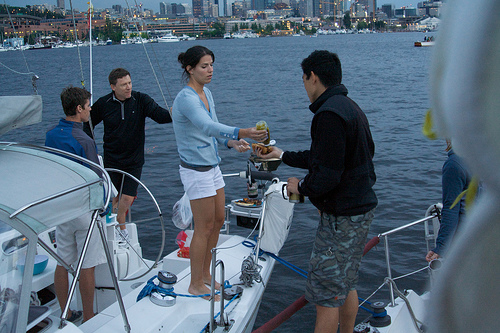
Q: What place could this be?
A: It is a harbor.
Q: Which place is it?
A: It is a harbor.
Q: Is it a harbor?
A: Yes, it is a harbor.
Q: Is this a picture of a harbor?
A: Yes, it is showing a harbor.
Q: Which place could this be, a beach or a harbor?
A: It is a harbor.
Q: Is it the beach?
A: No, it is the harbor.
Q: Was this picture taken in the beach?
A: No, the picture was taken in the harbor.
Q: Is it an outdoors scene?
A: Yes, it is outdoors.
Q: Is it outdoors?
A: Yes, it is outdoors.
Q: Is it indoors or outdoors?
A: It is outdoors.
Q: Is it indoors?
A: No, it is outdoors.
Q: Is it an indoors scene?
A: No, it is outdoors.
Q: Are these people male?
A: No, they are both male and female.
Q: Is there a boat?
A: Yes, there is a boat.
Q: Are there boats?
A: Yes, there is a boat.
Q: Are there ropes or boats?
A: Yes, there is a boat.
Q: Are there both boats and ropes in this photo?
A: Yes, there are both a boat and a rope.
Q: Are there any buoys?
A: No, there are no buoys.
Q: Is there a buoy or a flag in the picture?
A: No, there are no buoys or flags.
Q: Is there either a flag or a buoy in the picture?
A: No, there are no buoys or flags.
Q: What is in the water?
A: The boat is in the water.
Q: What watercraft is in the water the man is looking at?
A: The watercraft is a boat.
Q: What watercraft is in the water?
A: The watercraft is a boat.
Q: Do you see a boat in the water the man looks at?
A: Yes, there is a boat in the water.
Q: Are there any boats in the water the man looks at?
A: Yes, there is a boat in the water.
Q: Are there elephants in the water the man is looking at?
A: No, there is a boat in the water.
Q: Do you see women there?
A: Yes, there is a woman.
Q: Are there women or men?
A: Yes, there is a woman.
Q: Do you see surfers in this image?
A: No, there are no surfers.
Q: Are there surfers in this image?
A: No, there are no surfers.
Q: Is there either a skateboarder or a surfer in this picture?
A: No, there are no surfers or skateboarders.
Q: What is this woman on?
A: The woman is on the boat.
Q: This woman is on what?
A: The woman is on the boat.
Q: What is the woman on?
A: The woman is on the boat.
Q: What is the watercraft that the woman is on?
A: The watercraft is a boat.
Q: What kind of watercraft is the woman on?
A: The woman is on the boat.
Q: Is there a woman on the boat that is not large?
A: Yes, there is a woman on the boat.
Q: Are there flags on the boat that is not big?
A: No, there is a woman on the boat.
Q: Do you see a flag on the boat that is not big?
A: No, there is a woman on the boat.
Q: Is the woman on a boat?
A: Yes, the woman is on a boat.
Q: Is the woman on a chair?
A: No, the woman is on a boat.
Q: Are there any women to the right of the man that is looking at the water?
A: Yes, there is a woman to the right of the man.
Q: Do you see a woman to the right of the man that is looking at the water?
A: Yes, there is a woman to the right of the man.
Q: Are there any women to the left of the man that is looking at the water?
A: No, the woman is to the right of the man.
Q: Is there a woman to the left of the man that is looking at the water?
A: No, the woman is to the right of the man.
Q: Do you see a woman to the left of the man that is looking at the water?
A: No, the woman is to the right of the man.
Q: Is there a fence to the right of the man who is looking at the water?
A: No, there is a woman to the right of the man.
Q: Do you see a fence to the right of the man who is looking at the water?
A: No, there is a woman to the right of the man.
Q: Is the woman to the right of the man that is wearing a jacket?
A: Yes, the woman is to the right of the man.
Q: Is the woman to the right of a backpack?
A: No, the woman is to the right of the man.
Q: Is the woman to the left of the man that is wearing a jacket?
A: No, the woman is to the right of the man.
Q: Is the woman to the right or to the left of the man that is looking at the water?
A: The woman is to the right of the man.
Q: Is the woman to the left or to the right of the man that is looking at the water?
A: The woman is to the right of the man.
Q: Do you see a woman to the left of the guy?
A: Yes, there is a woman to the left of the guy.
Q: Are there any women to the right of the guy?
A: No, the woman is to the left of the guy.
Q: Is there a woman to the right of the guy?
A: No, the woman is to the left of the guy.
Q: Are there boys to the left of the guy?
A: No, there is a woman to the left of the guy.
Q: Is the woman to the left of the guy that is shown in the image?
A: Yes, the woman is to the left of the guy.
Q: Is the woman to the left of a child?
A: No, the woman is to the left of the guy.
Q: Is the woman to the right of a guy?
A: No, the woman is to the left of a guy.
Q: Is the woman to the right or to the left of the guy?
A: The woman is to the left of the guy.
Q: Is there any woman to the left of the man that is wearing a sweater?
A: Yes, there is a woman to the left of the man.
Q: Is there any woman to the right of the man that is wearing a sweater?
A: No, the woman is to the left of the man.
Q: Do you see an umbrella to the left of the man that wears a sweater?
A: No, there is a woman to the left of the man.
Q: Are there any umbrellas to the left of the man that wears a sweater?
A: No, there is a woman to the left of the man.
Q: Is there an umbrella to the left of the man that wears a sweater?
A: No, there is a woman to the left of the man.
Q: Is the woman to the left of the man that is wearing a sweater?
A: Yes, the woman is to the left of the man.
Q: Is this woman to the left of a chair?
A: No, the woman is to the left of the man.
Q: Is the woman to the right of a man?
A: No, the woman is to the left of a man.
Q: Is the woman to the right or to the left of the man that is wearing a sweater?
A: The woman is to the left of the man.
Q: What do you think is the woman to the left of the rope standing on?
A: The woman is standing on the boat.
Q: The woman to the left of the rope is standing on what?
A: The woman is standing on the boat.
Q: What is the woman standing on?
A: The woman is standing on the boat.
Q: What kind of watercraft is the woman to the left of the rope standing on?
A: The woman is standing on the boat.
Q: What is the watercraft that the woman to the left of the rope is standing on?
A: The watercraft is a boat.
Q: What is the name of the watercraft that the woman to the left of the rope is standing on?
A: The watercraft is a boat.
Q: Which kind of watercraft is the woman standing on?
A: The woman is standing on the boat.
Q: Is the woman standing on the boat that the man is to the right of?
A: Yes, the woman is standing on the boat.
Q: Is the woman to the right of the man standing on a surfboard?
A: No, the woman is standing on the boat.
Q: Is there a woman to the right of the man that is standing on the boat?
A: Yes, there is a woman to the right of the man.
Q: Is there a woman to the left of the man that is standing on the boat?
A: No, the woman is to the right of the man.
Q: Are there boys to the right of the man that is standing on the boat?
A: No, there is a woman to the right of the man.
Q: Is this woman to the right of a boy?
A: No, the woman is to the right of a man.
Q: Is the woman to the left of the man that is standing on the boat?
A: No, the woman is to the right of the man.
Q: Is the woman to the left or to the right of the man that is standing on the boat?
A: The woman is to the right of the man.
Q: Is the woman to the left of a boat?
A: Yes, the woman is to the left of a boat.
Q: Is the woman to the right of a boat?
A: No, the woman is to the left of a boat.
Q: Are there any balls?
A: No, there are no balls.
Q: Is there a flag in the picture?
A: No, there are no flags.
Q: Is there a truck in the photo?
A: No, there are no trucks.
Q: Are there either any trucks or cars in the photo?
A: No, there are no trucks or cars.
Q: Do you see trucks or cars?
A: No, there are no trucks or cars.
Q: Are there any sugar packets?
A: No, there are no sugar packets.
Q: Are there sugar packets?
A: No, there are no sugar packets.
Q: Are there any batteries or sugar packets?
A: No, there are no sugar packets or batteries.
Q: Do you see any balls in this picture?
A: No, there are no balls.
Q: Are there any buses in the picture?
A: No, there are no buses.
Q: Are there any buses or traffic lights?
A: No, there are no buses or traffic lights.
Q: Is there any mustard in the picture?
A: Yes, there is mustard.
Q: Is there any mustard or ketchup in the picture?
A: Yes, there is mustard.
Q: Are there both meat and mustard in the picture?
A: No, there is mustard but no meat.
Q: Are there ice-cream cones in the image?
A: No, there are no ice-cream cones.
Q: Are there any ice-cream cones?
A: No, there are no ice-cream cones.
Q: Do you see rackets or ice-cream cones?
A: No, there are no ice-cream cones or rackets.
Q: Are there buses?
A: No, there are no buses.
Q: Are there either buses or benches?
A: No, there are no buses or benches.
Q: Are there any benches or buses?
A: No, there are no buses or benches.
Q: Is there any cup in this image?
A: No, there are no cups.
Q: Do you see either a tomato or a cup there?
A: No, there are no cups or tomatoes.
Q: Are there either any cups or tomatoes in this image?
A: No, there are no cups or tomatoes.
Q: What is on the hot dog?
A: The condiment is on the hot dog.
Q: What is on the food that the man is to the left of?
A: The condiment is on the hot dog.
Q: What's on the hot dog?
A: The condiment is on the hot dog.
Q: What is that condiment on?
A: The condiment is on the hot dog.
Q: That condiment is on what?
A: The condiment is on the hot dog.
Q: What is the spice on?
A: The condiment is on the hot dog.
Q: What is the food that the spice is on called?
A: The food is a hot dog.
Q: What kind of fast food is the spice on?
A: The spice is on the hot dog.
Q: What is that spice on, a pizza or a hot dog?
A: The spice is on a hot dog.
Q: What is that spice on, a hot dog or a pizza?
A: The spice is on a hot dog.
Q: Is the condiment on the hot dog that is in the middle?
A: Yes, the condiment is on the hot dog.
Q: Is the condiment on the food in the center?
A: Yes, the condiment is on the hot dog.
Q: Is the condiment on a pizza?
A: No, the condiment is on the hot dog.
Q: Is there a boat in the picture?
A: Yes, there is a boat.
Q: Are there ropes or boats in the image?
A: Yes, there is a boat.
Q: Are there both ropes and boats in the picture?
A: Yes, there are both a boat and a rope.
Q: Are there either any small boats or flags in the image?
A: Yes, there is a small boat.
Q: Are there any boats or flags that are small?
A: Yes, the boat is small.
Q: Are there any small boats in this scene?
A: Yes, there is a small boat.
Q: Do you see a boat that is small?
A: Yes, there is a boat that is small.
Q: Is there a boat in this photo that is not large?
A: Yes, there is a small boat.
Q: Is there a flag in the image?
A: No, there are no flags.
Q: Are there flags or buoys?
A: No, there are no flags or buoys.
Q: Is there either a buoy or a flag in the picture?
A: No, there are no flags or buoys.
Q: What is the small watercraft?
A: The watercraft is a boat.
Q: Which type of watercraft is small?
A: The watercraft is a boat.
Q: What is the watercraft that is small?
A: The watercraft is a boat.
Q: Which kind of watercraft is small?
A: The watercraft is a boat.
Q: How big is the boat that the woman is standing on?
A: The boat is small.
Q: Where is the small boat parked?
A: The boat is parked at the harbor.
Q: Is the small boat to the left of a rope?
A: Yes, the boat is to the left of a rope.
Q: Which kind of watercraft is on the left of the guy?
A: The watercraft is a boat.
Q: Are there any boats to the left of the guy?
A: Yes, there is a boat to the left of the guy.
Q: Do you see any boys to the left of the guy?
A: No, there is a boat to the left of the guy.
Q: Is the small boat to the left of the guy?
A: Yes, the boat is to the left of the guy.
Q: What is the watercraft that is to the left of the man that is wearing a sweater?
A: The watercraft is a boat.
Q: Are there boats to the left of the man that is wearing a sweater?
A: Yes, there is a boat to the left of the man.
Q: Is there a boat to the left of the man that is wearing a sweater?
A: Yes, there is a boat to the left of the man.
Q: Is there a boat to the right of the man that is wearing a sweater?
A: No, the boat is to the left of the man.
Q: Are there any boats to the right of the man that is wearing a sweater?
A: No, the boat is to the left of the man.